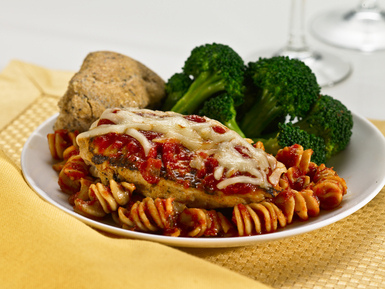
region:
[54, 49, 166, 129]
a chunk of brown bread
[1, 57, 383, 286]
a yellow placemat under a plate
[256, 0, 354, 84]
the stem of a wind glass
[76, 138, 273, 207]
a chicken breast on pasta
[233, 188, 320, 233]
a piece of spiral pasta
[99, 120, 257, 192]
red sauce on top of chicken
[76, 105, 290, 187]
melted white cheese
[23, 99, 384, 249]
a round white plate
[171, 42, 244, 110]
a piece of green broccoli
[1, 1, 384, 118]
a white table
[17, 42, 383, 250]
dinner on a white plate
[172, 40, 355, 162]
steamed broccoli pieces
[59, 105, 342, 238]
ziti and chicken with red sauce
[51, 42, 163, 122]
piece of multigrain bread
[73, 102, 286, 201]
chicken with tomato and mozzarella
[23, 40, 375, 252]
Italian dinner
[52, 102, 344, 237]
pasta and chicken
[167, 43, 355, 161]
side of vegetables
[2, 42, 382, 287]
dinner plate on a yellow place mat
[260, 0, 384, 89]
stems of win glasses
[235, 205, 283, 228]
pasta on the plate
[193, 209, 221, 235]
pasta on the plate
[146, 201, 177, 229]
pasta on the plate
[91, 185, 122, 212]
pasta on the plate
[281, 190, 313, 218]
pasta on the plate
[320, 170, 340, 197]
pasta on the plate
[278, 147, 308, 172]
pasta on the plate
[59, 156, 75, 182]
pasta on the plate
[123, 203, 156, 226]
pasta on the plate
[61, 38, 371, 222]
A piece of delicious meal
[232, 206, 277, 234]
A delicious cooked nodules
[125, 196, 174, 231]
A delicious cooked nodules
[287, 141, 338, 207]
A delicious cooked nodules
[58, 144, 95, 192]
A delicious cooked nodules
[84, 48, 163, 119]
A piece of brown bread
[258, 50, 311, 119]
A green piece of vegitable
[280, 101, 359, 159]
A green piece of vegitable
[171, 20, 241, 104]
A green piece of vegitable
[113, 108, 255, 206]
A piece of fried chicken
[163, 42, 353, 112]
broccoli spears on the dinner plate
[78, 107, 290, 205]
baked chicken with sauce and cheese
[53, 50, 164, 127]
bread served on the dinner plate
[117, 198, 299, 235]
pasta and sauce on a plate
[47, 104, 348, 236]
chicken and pasta served with broccoli and bread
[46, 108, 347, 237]
chicken on top of pasta and sauce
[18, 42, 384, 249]
Dinner served in a restaurant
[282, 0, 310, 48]
the stem of a glassware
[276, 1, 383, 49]
two stems to glasses on the table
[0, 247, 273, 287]
a yellow napkin on the table